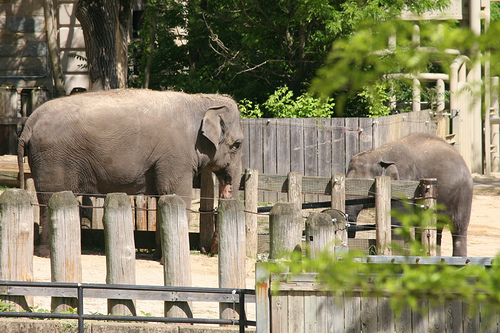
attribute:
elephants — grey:
[23, 103, 477, 283]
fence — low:
[3, 139, 486, 293]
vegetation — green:
[139, 12, 495, 142]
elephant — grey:
[36, 46, 252, 267]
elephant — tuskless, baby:
[345, 121, 485, 279]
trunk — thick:
[205, 112, 261, 248]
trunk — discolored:
[201, 157, 279, 262]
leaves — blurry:
[245, 197, 499, 320]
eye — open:
[216, 106, 263, 200]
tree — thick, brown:
[68, 3, 168, 234]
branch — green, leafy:
[302, 13, 497, 111]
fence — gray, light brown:
[257, 253, 497, 330]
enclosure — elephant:
[3, 45, 493, 329]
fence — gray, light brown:
[0, 173, 453, 330]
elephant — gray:
[14, 86, 248, 260]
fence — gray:
[242, 105, 443, 203]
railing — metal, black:
[2, 279, 250, 330]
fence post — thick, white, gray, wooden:
[154, 191, 191, 319]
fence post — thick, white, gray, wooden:
[43, 187, 88, 314]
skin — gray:
[89, 114, 137, 164]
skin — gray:
[389, 147, 409, 169]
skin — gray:
[192, 104, 205, 132]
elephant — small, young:
[342, 129, 475, 253]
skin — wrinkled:
[74, 149, 157, 192]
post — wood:
[215, 170, 250, 329]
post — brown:
[197, 189, 257, 325]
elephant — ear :
[193, 100, 227, 156]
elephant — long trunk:
[219, 145, 258, 218]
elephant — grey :
[13, 68, 253, 248]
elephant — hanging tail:
[25, 78, 259, 250]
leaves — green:
[339, 262, 456, 288]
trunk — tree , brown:
[55, 58, 89, 78]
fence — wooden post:
[2, 181, 422, 320]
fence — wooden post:
[240, 102, 439, 189]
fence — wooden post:
[242, 104, 442, 174]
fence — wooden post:
[242, 101, 452, 187]